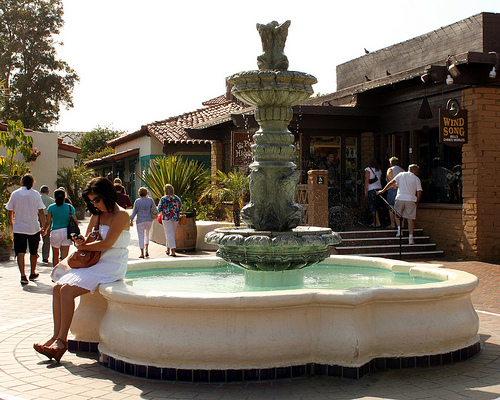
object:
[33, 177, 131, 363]
woman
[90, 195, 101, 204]
sunglasses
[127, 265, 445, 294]
water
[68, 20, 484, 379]
fountain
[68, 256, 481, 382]
basin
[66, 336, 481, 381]
brick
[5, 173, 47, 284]
man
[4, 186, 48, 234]
shirt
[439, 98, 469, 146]
sign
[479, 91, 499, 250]
wall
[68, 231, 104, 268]
purse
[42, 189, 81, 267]
woman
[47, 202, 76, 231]
shirt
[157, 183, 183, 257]
woman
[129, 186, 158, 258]
woman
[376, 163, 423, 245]
man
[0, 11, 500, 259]
building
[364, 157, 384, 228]
woman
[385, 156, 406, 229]
woman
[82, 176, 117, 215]
hair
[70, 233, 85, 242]
cellphone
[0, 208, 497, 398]
plaza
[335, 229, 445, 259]
stairs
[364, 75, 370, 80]
bird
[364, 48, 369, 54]
bird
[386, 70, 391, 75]
bird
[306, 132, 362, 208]
entrance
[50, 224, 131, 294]
dress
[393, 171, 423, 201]
shirt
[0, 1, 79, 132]
tree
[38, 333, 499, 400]
shadow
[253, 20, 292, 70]
statue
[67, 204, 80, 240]
purse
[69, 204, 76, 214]
shoulder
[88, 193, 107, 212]
face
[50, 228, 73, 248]
shorts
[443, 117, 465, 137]
letters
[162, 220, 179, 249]
pants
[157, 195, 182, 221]
shirt